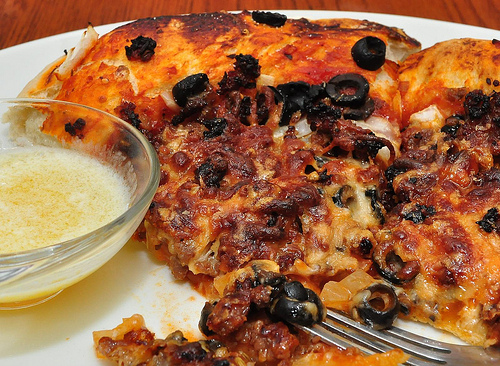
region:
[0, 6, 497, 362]
The pieces of pizza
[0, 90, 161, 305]
The small clear glass bowl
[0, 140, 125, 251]
The butter in the bowl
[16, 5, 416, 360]
The slice of pizza on the left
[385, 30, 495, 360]
The slice of pizza on the right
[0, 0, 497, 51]
The table the pizza is on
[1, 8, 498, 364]
The plate the pizza is on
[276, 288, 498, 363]
The fork in the pizza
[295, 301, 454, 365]
The prongs of the fork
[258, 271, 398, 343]
The olives touching the fork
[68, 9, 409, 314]
a slice of pizza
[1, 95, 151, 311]
a glass bowl next to pizza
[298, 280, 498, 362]
a fork in a pizza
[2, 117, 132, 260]
a dipping sauce in a bowl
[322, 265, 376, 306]
two diced onions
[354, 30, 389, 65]
a black olive on a crust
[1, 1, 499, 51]
a brown wood table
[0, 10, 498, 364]
a white plate holding a pizza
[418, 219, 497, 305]
melted cheese on a pizza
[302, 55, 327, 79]
red sauce on a pizza crust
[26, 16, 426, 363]
two slices of pizza on white plate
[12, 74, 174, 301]
glass bowl on white plate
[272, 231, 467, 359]
silver metal fork on pizza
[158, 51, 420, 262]
black olives on two slices of pizza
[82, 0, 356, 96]
crust of pizza slightly burnt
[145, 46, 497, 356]
cheese on pizza slightly burnt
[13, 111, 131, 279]
yellowish-whitish sauce in glass bowl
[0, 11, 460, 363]
plate with pizza on it on brown table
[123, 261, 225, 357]
pizza grease on white plate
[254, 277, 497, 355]
fork being used on black olive pizza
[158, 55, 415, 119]
many black olives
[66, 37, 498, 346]
the food is black and red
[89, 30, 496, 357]
the food is half eaten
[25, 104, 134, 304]
the sauce is melted butter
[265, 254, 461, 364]
the fork is in the food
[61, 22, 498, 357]
the food has olives in it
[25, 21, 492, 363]
the food is on a plate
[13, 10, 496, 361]
the plate is on the table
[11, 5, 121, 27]
the table is wood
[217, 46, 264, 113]
part of a pizza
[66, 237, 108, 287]
part of a bowl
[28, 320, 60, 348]
part of a table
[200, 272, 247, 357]
edge of a pizza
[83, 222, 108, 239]
edge of a bowl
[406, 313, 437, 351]
part of a fork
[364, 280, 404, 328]
part of an onion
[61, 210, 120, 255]
edge of a bowl